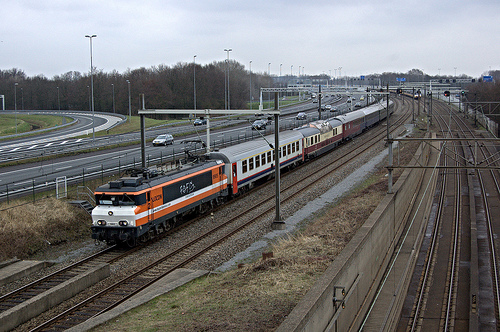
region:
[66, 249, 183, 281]
gravel between train tracks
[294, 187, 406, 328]
a tall cement barrier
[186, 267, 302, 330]
patches of grass and dirt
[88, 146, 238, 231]
an orange and white train engine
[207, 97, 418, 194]
a line of train cars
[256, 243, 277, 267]
a short stump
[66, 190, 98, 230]
a set of cement stairs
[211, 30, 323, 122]
a few street lights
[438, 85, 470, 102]
two different street lights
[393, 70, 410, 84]
a blue billboard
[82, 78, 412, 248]
Train on a rail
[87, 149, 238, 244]
Engine train is orange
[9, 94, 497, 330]
Several rails on soil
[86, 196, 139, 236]
Front of train is white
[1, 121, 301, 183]
Highway on left side of train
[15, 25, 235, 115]
Light poles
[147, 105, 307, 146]
Cars traveling in the highway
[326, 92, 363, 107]
Cars in the background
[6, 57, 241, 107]
Trees on back of road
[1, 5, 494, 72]
Sky is filled of clouds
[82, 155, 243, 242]
orange and white train engine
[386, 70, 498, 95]
blue traffic signs over a transit area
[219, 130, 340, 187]
passenger train cars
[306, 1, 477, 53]
grey and cloudy sky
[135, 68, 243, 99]
leafless brown trees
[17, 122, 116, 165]
highway lanes and ramps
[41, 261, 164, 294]
dual rail lines for trains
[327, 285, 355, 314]
signals to direct trains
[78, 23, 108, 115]
stadium style lighting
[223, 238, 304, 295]
gravel, dead grass, and a tree stump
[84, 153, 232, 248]
orange black and white engine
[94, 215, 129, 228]
headlights on an engine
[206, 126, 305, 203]
pale gray carriage being pulled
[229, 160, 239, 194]
red door in a train carriage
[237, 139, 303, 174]
eleven windows in a train carriage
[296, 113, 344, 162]
dark red, cream and gray carriage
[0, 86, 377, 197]
motorway next to train tracks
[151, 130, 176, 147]
car is driving on the motorway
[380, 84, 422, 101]
a second train is approaching in the distance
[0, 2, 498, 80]
sky is pale and cloudy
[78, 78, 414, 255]
Passenger train running on rail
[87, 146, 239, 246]
Front car is orange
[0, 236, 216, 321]
Rails on the ground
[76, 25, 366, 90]
Light poles on side of highway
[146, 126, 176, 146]
White car on the highway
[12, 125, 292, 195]
Highway next to train rails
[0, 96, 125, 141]
Road that converge with highway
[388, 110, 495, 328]
Rails in the lower level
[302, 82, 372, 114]
Cars running in the highway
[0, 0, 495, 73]
sky is grey